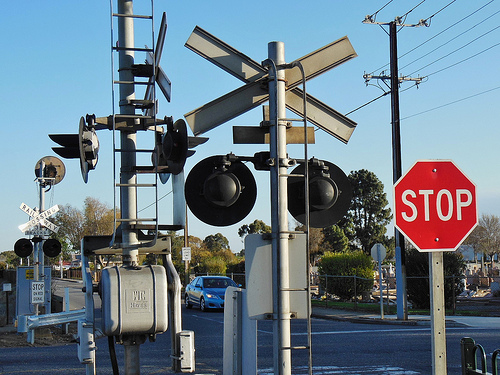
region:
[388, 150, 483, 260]
a red and white stop sign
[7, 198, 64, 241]
a railroad crossing sign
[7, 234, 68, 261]
the railroad crossing lights are off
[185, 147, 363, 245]
the back of railroad crossing lights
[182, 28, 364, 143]
the back of a railroad crossing sign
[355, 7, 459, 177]
a tall wood utility line pole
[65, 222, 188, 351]
the machine that operates the bar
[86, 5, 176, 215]
a car blocking bar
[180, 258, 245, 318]
a silver car driving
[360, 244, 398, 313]
the back of a stop sign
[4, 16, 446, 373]
a railroad crossing area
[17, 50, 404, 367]
a railroad crossing caution lights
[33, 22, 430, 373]
railroad caution lights on a pole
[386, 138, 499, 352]
a stop sign on a pole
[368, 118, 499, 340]
a stop sign on a metal pole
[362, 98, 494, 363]
a red and white sign on a pole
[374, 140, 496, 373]
a red and white sign on a metal pole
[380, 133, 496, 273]
a red and white sign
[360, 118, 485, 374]
a pole with a stop sign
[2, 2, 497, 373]
A railroad crossing scene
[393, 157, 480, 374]
This is a stop sign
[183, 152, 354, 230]
Railroad crossing signal lights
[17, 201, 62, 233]
A railroad crossing sign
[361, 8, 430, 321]
A telephone pole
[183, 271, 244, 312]
A car is stopped at the crossing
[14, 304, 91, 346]
This is a guard rail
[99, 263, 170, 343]
A control box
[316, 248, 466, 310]
Bushes are growing in the background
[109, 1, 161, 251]
A ladder is on the pole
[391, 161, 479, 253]
A red and white stop sign.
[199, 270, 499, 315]
A grey chainlink fence.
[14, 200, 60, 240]
A white and black railroad crossing sign.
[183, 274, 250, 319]
A four-door car.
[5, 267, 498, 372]
The street.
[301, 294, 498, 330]
The sidewalk.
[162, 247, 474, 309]
Green bushes.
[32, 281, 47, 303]
A black and white street sign.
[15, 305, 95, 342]
A silver guard rail.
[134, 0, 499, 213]
Power lines above the road.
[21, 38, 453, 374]
the poles are grey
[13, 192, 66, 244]
this is a rail road crossing sign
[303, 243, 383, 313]
this bush is trimmed into a funny shape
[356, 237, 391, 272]
this is a stop sign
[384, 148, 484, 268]
this sign is red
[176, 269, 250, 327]
this is a car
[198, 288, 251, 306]
the car's lights are on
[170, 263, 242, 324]
the car is silver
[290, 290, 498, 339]
this is a sidewalk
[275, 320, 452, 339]
the white lines are painted on the pavement